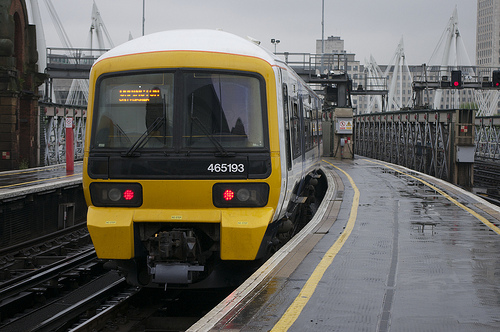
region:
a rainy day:
[19, 11, 496, 326]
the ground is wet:
[322, 143, 492, 324]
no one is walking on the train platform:
[317, 116, 494, 330]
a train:
[71, 34, 356, 290]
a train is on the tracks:
[77, 30, 353, 301]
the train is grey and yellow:
[81, 24, 333, 292]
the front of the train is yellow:
[88, 27, 290, 273]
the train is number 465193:
[89, 147, 276, 187]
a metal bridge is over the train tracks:
[46, 36, 398, 88]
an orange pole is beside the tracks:
[51, 109, 81, 179]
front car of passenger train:
[82, 23, 326, 279]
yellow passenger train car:
[82, 33, 292, 284]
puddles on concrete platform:
[369, 155, 454, 252]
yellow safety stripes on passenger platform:
[257, 174, 385, 326]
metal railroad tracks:
[5, 231, 87, 298]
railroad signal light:
[445, 64, 466, 94]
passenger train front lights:
[82, 177, 276, 217]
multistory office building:
[474, 1, 499, 88]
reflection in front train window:
[96, 72, 256, 148]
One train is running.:
[86, 46, 293, 286]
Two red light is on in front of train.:
[116, 182, 246, 216]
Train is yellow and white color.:
[170, 27, 315, 245]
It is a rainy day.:
[19, 61, 479, 305]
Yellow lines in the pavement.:
[301, 194, 499, 276]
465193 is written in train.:
[201, 158, 262, 185]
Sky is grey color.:
[184, 4, 420, 33]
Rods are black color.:
[364, 108, 460, 165]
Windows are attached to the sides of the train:
[279, 81, 320, 172]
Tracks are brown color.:
[2, 245, 157, 329]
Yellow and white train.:
[85, 42, 319, 265]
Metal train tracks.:
[11, 243, 90, 315]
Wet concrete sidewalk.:
[358, 174, 460, 273]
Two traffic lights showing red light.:
[442, 64, 499, 108]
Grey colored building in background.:
[312, 32, 354, 83]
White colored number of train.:
[203, 157, 268, 177]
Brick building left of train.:
[3, 2, 45, 159]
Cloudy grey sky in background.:
[208, 7, 315, 37]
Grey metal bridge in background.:
[43, 42, 355, 84]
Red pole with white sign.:
[60, 112, 80, 186]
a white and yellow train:
[51, 15, 383, 298]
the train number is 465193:
[193, 142, 267, 197]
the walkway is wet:
[274, 130, 498, 327]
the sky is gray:
[29, 1, 498, 78]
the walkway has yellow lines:
[267, 136, 494, 329]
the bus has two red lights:
[76, 160, 300, 260]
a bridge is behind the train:
[28, 35, 496, 127]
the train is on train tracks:
[38, 27, 348, 329]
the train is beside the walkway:
[66, 28, 495, 328]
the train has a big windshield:
[82, 44, 281, 239]